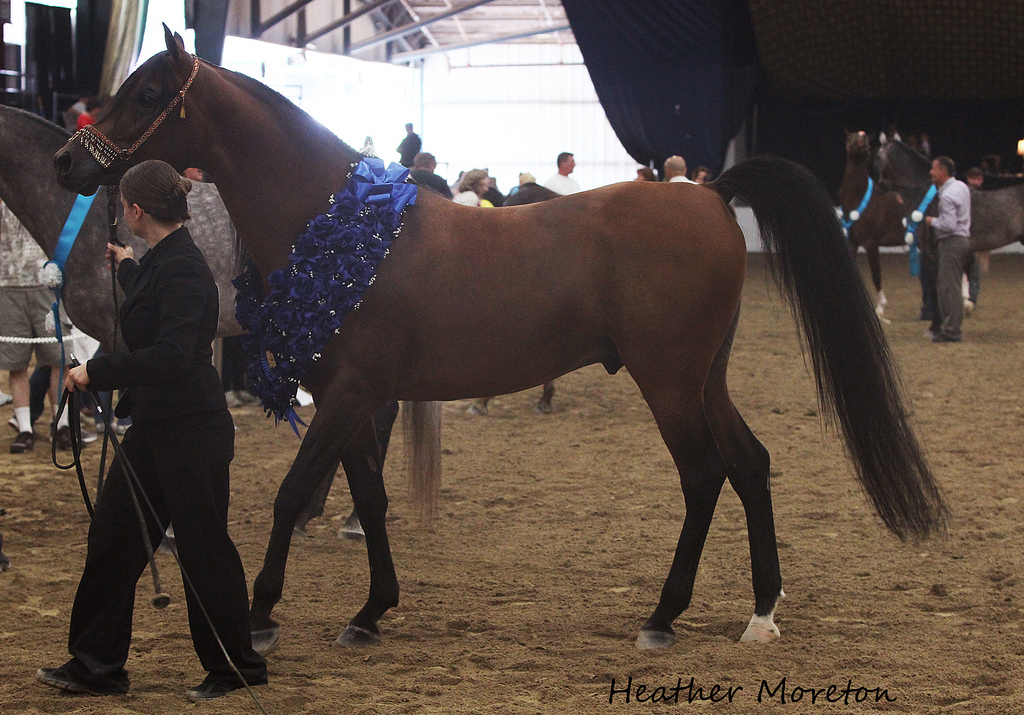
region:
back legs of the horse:
[642, 473, 783, 635]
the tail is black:
[802, 282, 879, 396]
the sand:
[481, 531, 595, 623]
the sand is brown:
[477, 491, 607, 610]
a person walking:
[44, 258, 263, 704]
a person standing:
[927, 160, 978, 339]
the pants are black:
[104, 422, 248, 672]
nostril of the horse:
[51, 146, 86, 179]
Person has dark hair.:
[122, 164, 211, 251]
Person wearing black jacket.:
[88, 262, 234, 415]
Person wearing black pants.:
[69, 416, 253, 676]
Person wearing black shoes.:
[25, 648, 264, 706]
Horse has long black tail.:
[698, 142, 949, 553]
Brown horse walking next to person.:
[76, 66, 775, 632]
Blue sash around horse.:
[268, 155, 389, 427]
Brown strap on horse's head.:
[125, 70, 201, 165]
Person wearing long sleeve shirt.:
[928, 179, 970, 243]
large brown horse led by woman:
[100, 49, 926, 691]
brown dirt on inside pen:
[441, 489, 503, 537]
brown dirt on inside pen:
[478, 653, 514, 677]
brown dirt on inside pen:
[368, 646, 401, 662]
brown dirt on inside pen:
[495, 573, 531, 606]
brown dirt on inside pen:
[527, 481, 572, 532]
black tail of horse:
[759, 148, 979, 564]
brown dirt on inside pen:
[522, 535, 555, 575]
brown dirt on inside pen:
[821, 647, 876, 692]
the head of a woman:
[113, 169, 194, 283]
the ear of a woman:
[113, 186, 183, 257]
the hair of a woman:
[111, 151, 203, 270]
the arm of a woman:
[43, 245, 256, 470]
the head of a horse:
[51, 24, 264, 217]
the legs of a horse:
[580, 302, 816, 660]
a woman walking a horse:
[27, 18, 797, 712]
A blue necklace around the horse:
[231, 139, 428, 408]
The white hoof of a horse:
[739, 584, 797, 654]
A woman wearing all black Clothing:
[43, 143, 284, 703]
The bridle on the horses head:
[60, 58, 219, 160]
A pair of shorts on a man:
[5, 278, 76, 386]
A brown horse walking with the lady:
[38, 18, 816, 704]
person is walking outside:
[119, 160, 186, 231]